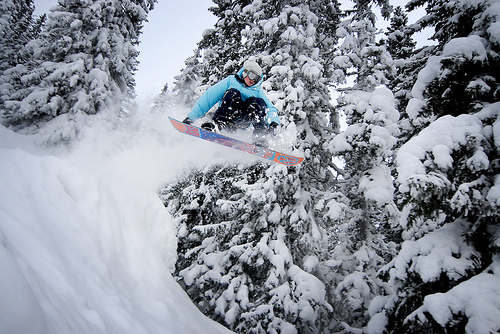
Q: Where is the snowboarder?
A: The snowboarder is in the air.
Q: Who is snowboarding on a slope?
A: A boy is snowboarding on a slope.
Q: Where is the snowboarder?
A: The snowboarder is in the air on his board.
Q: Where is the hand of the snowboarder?
A: The snowboarder has a hand on the back of the board.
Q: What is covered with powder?
A: The steep slope is covered with powder.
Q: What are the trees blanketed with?
A: The trees are blanketed with snow.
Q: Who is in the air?
A: A snowboarder is in the air.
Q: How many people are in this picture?
A: One.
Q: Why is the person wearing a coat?
A: Cold outside.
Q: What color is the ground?
A: White.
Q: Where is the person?
A: In the air.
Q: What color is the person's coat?
A: Blue.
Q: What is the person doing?
A: Snowboarding.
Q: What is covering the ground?
A: Snow.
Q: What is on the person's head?
A: A hat.